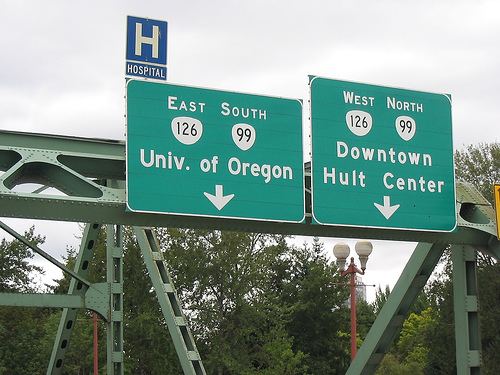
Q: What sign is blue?
A: The hospital.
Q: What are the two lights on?
A: A brown pole.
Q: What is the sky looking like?
A: Kind of clear.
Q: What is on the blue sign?
A: A big h.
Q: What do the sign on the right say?
A: Downtown hult center.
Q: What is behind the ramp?
A: Tall trees.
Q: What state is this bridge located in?
A: Oregon.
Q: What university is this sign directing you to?
A: University of Oregon.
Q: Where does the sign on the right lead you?
A: Downtown.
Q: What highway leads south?
A: 99.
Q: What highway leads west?
A: 126.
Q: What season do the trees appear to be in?
A: Summer.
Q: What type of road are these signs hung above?
A: Highway.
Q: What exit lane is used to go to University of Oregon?
A: Left.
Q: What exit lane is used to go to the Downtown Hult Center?
A: Right.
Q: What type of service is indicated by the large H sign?
A: Hospital.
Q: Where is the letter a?
A: On an interstate sign.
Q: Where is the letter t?
A: On an interstate sign.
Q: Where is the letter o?
A: On an interstate sign.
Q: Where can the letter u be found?
A: On an interstate sign.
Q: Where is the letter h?
A: On an interstate sign.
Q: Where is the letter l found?
A: On an interstate sign.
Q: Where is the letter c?
A: On an interstate sign.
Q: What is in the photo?
A: Road posts.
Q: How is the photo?
A: Clear.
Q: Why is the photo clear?
A: Its during the day.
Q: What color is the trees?
A: Green.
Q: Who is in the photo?
A: No one.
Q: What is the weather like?
A: Calm.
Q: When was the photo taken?
A: Daytime.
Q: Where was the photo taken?
A: On a interstate.